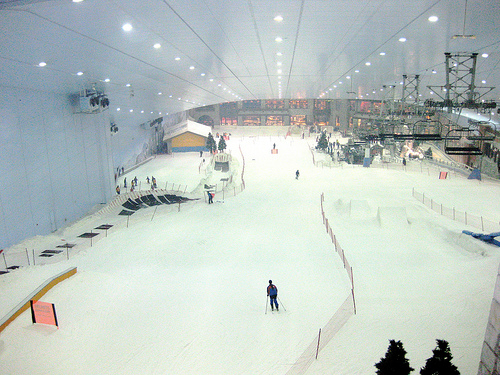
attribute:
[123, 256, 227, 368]
white snow — clear, clean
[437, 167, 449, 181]
object — orange, blue